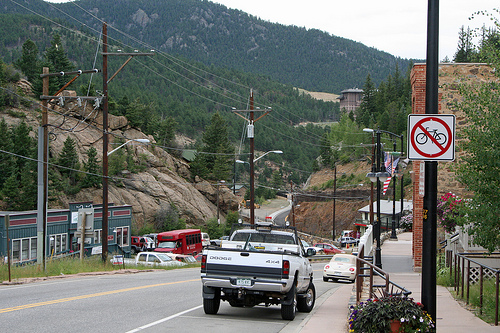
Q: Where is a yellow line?
A: On the street.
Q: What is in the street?
A: Vehicles.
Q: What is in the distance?
A: Trees.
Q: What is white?
A: Truck.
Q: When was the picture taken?
A: Daytime.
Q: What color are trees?
A: Green.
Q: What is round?
A: Tires.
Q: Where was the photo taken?
A: On a street.